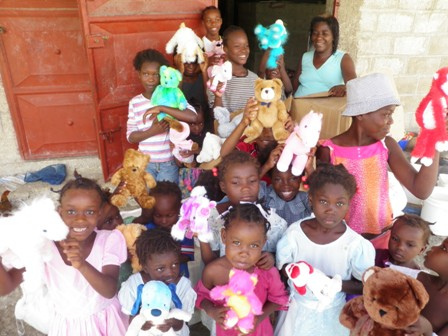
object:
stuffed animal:
[253, 19, 289, 71]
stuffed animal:
[242, 77, 291, 144]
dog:
[285, 260, 344, 309]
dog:
[121, 279, 183, 336]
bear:
[209, 266, 265, 334]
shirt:
[317, 137, 396, 234]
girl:
[316, 72, 448, 249]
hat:
[340, 72, 402, 117]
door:
[75, 0, 220, 186]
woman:
[275, 15, 357, 99]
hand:
[328, 83, 345, 97]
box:
[284, 92, 352, 138]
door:
[0, 0, 97, 161]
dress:
[14, 228, 129, 336]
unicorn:
[0, 196, 69, 272]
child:
[0, 168, 128, 336]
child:
[117, 227, 198, 336]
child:
[194, 203, 290, 336]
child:
[274, 162, 378, 336]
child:
[125, 48, 198, 182]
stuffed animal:
[339, 265, 434, 336]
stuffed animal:
[284, 259, 344, 313]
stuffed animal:
[123, 280, 194, 336]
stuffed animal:
[276, 110, 323, 176]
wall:
[330, 0, 447, 145]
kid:
[220, 96, 294, 186]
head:
[255, 126, 276, 149]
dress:
[315, 137, 395, 237]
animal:
[150, 65, 187, 122]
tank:
[293, 51, 349, 98]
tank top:
[292, 48, 347, 98]